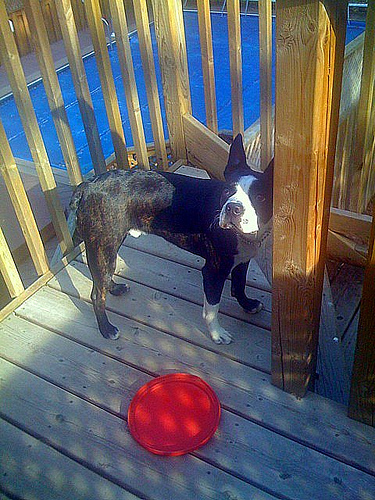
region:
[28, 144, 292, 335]
the dog is looking up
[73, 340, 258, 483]
a frisbee is on the floor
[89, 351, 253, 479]
the frisbee is red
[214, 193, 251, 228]
the nose is black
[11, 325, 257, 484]
the ground is grey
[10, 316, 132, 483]
the floor is made of wood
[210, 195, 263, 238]
sun partially on the dogs face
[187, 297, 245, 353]
one paw is white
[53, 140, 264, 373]
the dog is black and white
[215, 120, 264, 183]
the ear is pointy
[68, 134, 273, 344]
a black and white bulldog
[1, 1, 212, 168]
a wood railing on the deck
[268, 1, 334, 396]
a wooden verticle column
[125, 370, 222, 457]
a red plastic bucket top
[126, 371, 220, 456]
a red Frisbee disk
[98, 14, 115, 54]
a metal swimming pool ladder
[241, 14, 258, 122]
the blue water in a swimming pool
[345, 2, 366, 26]
a PVC water polo net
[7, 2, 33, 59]
a wooden privacy fence around the swimming pool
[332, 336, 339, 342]
a galvanized bolt securing the wood deck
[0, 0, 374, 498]
an outdoor wooden deck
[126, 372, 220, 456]
a red frisbee on the deck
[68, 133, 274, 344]
a dog on the deck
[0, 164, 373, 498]
the wood floor of the deck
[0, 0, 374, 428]
the wood railings of the deck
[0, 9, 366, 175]
a swimming pool in the background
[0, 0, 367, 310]
an area of ground around the pool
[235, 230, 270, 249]
the dog's collar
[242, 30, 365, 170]
a wooden fence down below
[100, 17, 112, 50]
a railing in the pool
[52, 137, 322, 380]
a small dog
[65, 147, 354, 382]
a black and white dog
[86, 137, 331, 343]
a white and black dog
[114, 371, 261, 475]
a red frisbee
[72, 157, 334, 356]
a dog wearing a collar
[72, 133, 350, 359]
a dog standing on a deck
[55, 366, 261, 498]
a frisbee on a wooden deck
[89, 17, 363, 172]
a wooden deck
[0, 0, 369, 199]
a in ground swiming pool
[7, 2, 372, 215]
a swimming pool